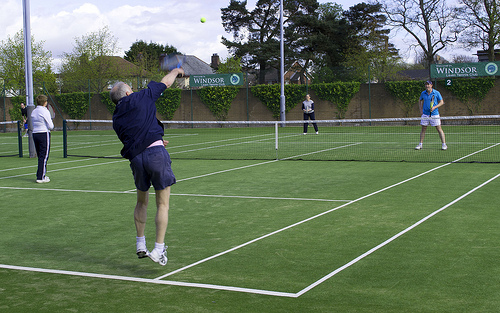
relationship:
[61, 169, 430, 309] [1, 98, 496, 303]
lines on court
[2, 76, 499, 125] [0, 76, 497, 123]
grass on wall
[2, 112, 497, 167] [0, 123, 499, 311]
net in between court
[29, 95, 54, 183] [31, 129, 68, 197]
person wearing pants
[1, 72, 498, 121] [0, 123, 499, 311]
wall behind court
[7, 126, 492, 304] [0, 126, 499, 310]
lines drawn on court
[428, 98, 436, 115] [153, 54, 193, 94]
racket in hand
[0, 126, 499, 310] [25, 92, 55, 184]
court with person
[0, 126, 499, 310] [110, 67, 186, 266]
court with man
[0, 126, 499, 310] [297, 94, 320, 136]
court with person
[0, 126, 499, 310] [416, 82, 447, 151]
court with man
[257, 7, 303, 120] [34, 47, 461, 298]
lights poles around tennis courts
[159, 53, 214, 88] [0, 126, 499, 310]
house behind court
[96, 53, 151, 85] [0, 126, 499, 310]
house behind court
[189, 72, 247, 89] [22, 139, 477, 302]
sign for courts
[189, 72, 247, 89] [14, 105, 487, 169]
sign for courts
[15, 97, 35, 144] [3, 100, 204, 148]
person on tennis court